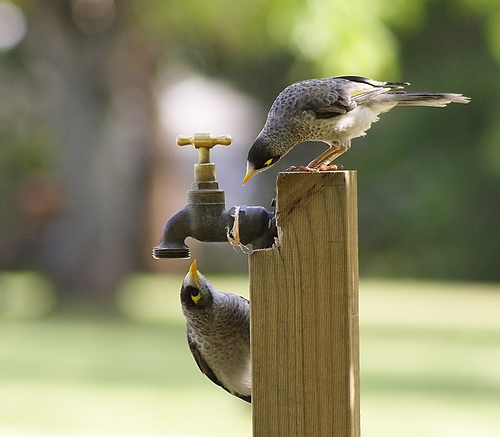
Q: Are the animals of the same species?
A: Yes, all the animals are birds.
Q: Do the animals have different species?
A: No, all the animals are birds.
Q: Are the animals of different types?
A: No, all the animals are birds.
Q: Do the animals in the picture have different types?
A: No, all the animals are birds.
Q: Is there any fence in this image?
A: No, there are no fences.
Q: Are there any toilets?
A: No, there are no toilets.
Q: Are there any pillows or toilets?
A: No, there are no toilets or pillows.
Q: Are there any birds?
A: Yes, there is a bird.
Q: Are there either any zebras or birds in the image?
A: Yes, there is a bird.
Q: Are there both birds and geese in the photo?
A: No, there is a bird but no geese.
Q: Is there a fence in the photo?
A: No, there are no fences.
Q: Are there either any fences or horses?
A: No, there are no fences or horses.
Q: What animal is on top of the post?
A: The bird is on top of the post.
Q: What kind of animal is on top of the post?
A: The animal is a bird.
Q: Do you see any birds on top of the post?
A: Yes, there is a bird on top of the post.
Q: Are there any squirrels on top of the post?
A: No, there is a bird on top of the post.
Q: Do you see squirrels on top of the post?
A: No, there is a bird on top of the post.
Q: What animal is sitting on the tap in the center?
A: The bird is sitting on the faucet.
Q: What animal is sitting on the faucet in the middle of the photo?
A: The animal is a bird.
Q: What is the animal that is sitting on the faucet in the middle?
A: The animal is a bird.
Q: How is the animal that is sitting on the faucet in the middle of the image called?
A: The animal is a bird.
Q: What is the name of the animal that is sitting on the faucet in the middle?
A: The animal is a bird.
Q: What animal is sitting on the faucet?
A: The animal is a bird.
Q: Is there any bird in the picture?
A: Yes, there is a bird.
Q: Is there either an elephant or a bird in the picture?
A: Yes, there is a bird.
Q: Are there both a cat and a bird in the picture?
A: No, there is a bird but no cats.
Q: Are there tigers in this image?
A: No, there are no tigers.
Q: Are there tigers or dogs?
A: No, there are no tigers or dogs.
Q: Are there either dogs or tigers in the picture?
A: No, there are no tigers or dogs.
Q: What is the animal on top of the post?
A: The animal is a bird.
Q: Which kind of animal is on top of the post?
A: The animal is a bird.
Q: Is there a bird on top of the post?
A: Yes, there is a bird on top of the post.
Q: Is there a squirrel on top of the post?
A: No, there is a bird on top of the post.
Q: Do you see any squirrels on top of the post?
A: No, there is a bird on top of the post.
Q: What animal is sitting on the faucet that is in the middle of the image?
A: The bird is sitting on the faucet.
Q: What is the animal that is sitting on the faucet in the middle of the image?
A: The animal is a bird.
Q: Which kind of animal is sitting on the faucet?
A: The animal is a bird.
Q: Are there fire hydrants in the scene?
A: No, there are no fire hydrants.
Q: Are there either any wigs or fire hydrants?
A: No, there are no fire hydrants or wigs.